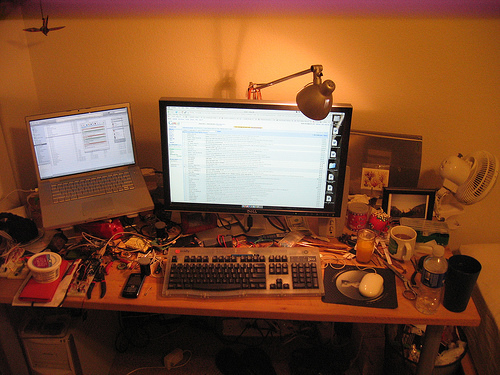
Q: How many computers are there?
A: 2.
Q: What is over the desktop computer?
A: Lamp.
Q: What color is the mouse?
A: White.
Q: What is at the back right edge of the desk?
A: Fan.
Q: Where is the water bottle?
A: Right of the mouse.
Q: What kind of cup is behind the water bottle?
A: Coffee cup.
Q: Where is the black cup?
A: Right of the water bottle.